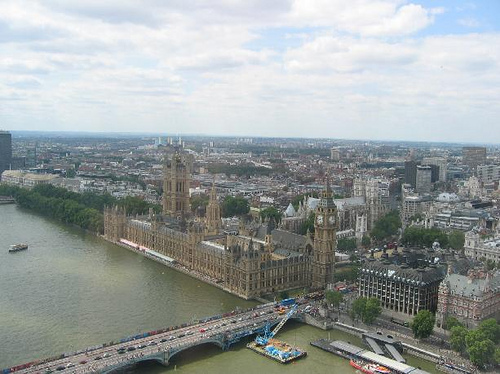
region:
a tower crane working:
[250, 305, 306, 363]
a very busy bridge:
[36, 331, 229, 373]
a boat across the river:
[8, 239, 31, 257]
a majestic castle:
[97, 148, 337, 295]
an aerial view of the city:
[26, 129, 498, 371]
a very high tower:
[306, 177, 336, 294]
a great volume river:
[5, 269, 192, 326]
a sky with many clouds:
[51, 4, 496, 135]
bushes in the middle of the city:
[19, 182, 104, 227]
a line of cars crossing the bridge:
[89, 338, 181, 360]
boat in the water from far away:
[3, 234, 59, 284]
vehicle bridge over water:
[2, 302, 282, 372]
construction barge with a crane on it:
[248, 301, 308, 366]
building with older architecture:
[99, 148, 341, 300]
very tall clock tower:
[309, 173, 340, 293]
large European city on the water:
[0, 66, 497, 372]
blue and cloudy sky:
[2, 2, 499, 130]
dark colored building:
[353, 251, 447, 339]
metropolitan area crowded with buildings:
[338, 143, 498, 253]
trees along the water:
[13, 191, 87, 237]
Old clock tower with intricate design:
[314, 180, 338, 292]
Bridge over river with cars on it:
[4, 299, 304, 371]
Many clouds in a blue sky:
[0, 2, 498, 132]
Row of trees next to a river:
[13, 181, 123, 226]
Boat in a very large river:
[4, 239, 34, 256]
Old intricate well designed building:
[99, 148, 342, 301]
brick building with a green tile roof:
[437, 255, 498, 333]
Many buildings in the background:
[333, 142, 498, 232]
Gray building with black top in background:
[415, 161, 432, 196]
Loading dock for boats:
[315, 329, 417, 372]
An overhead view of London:
[6, 12, 494, 367]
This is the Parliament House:
[98, 152, 342, 296]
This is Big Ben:
[306, 173, 340, 289]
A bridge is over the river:
[6, 294, 303, 372]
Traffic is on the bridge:
[30, 306, 262, 372]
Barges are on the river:
[247, 323, 428, 372]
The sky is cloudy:
[1, 5, 496, 131]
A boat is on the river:
[6, 237, 34, 257]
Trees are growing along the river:
[11, 180, 106, 236]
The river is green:
[3, 259, 288, 371]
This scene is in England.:
[8, 85, 465, 362]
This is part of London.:
[291, 160, 496, 312]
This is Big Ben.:
[297, 166, 344, 298]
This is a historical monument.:
[128, 168, 348, 293]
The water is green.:
[16, 262, 186, 330]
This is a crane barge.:
[251, 324, 313, 371]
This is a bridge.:
[6, 298, 282, 356]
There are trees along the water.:
[28, 180, 103, 225]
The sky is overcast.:
[82, 95, 378, 131]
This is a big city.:
[21, 120, 492, 337]